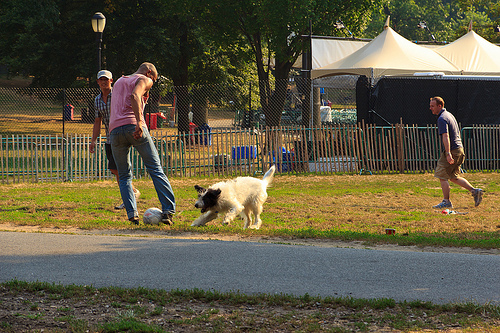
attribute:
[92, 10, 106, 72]
lamp — nice black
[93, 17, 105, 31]
globe — glass 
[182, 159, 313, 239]
dog — black, white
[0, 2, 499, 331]
park — scene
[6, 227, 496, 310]
path — paved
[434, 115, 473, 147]
shirt — blue, polo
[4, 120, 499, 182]
fencing — brown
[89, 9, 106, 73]
lamppost — tall, black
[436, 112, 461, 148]
tee shirt — blue short sleeve 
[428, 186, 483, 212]
tennis shoes — pair 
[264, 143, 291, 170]
object — blue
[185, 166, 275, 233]
dog — brown, white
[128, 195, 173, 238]
ball — soccer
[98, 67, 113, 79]
hat — white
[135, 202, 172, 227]
ball — white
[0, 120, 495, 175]
fence — wire silver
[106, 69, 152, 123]
shirt — pink tee 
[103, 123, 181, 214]
jeans — blue 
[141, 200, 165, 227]
ball — soccer 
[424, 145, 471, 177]
shorts — brown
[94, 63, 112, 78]
cap — nice black